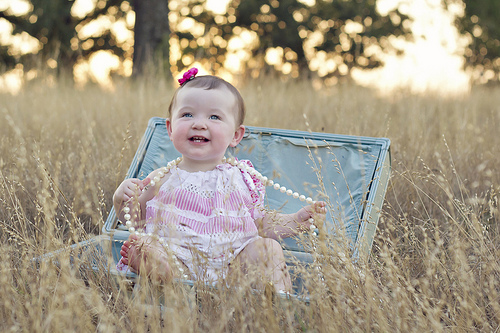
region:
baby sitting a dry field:
[101, 55, 386, 312]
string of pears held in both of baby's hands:
[109, 170, 330, 235]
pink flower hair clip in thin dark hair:
[159, 61, 252, 162]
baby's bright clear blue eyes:
[173, 100, 225, 130]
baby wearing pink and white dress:
[132, 144, 287, 289]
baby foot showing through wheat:
[109, 232, 179, 298]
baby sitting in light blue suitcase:
[98, 75, 393, 325]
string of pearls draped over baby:
[108, 81, 328, 292]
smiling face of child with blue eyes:
[156, 56, 253, 163]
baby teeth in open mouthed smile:
[177, 130, 214, 153]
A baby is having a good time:
[15, 32, 470, 308]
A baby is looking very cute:
[20, 50, 480, 330]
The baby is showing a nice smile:
[25, 38, 495, 318]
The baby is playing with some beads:
[22, 20, 487, 295]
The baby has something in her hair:
[25, 28, 465, 304]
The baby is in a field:
[10, 53, 476, 314]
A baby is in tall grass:
[18, 25, 484, 296]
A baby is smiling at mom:
[13, 30, 475, 330]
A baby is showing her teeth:
[11, 27, 476, 318]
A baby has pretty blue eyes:
[10, 43, 497, 324]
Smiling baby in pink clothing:
[113, 74, 304, 308]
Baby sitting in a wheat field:
[415, 96, 498, 265]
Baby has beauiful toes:
[113, 230, 176, 284]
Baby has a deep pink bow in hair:
[171, 67, 205, 83]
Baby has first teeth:
[183, 132, 211, 144]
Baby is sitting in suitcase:
[37, 111, 397, 297]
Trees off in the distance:
[23, 6, 426, 67]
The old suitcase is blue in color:
[101, 103, 375, 273]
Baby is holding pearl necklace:
[243, 167, 315, 200]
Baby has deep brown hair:
[184, 73, 242, 91]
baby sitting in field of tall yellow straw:
[110, 63, 329, 318]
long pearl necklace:
[119, 141, 320, 286]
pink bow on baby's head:
[169, 58, 204, 85]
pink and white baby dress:
[136, 158, 276, 276]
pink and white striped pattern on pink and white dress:
[155, 184, 250, 216]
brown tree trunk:
[121, 0, 176, 106]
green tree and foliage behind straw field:
[437, 1, 497, 98]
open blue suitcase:
[31, 96, 396, 318]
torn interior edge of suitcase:
[272, 133, 358, 158]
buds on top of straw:
[2, 171, 73, 331]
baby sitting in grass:
[110, 70, 328, 311]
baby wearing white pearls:
[114, 68, 329, 308]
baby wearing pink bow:
[115, 65, 324, 320]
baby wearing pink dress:
[110, 67, 329, 322]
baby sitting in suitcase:
[50, 68, 385, 322]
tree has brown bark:
[125, 0, 180, 91]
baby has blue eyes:
[178, 108, 226, 125]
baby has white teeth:
[183, 130, 216, 150]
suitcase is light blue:
[37, 115, 394, 314]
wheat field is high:
[1, 93, 496, 328]